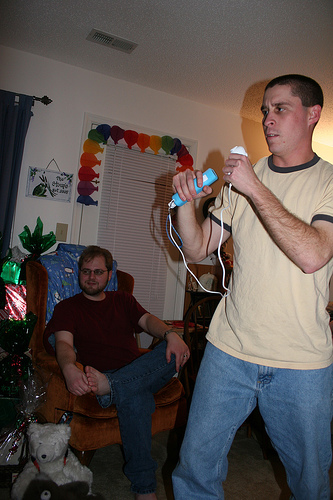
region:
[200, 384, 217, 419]
man wearing blue jeans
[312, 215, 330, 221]
blue lining on sleeve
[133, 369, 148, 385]
man wearing dark blue jeans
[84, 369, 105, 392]
man with bare foot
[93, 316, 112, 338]
man wearing burgandy tshirt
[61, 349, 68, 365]
man has hair on arm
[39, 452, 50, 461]
bear has black nose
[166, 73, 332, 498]
man playing a game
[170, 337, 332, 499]
the pants are blue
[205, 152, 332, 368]
a black and yellow shirt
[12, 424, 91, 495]
teddy bear on floor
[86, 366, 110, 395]
the man is barefoot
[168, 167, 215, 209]
blue and white controller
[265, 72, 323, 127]
the hair is short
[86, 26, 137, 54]
vent on the ceiling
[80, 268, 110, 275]
the man has glasses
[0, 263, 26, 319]
a wrapped present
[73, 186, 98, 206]
paper balloon over window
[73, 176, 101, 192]
paper balloon over window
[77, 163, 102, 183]
paper balloon over window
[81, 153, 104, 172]
paper balloon over window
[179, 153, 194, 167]
paper balloon over window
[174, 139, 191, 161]
paper balloon over window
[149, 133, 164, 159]
paper balloon over window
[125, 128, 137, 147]
paper balloon over window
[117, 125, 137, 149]
paper balloon over window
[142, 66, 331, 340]
man holding game controls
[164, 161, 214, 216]
game control is blue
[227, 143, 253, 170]
game control is white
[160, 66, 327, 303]
man has short hair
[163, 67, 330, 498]
man wears blue jeans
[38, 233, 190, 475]
man sits on a chair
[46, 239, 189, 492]
man cross his legs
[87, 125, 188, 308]
the window has blinds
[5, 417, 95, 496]
a white teddy bear on the floor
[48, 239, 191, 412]
man wears glasses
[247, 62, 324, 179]
head of a person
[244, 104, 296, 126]
eye of a person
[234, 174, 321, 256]
arm of a person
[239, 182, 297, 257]
an arm of a person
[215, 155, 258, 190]
hand of a person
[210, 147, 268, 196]
a hand of a person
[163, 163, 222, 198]
hand of a person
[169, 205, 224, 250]
arm of a person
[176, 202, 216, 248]
an arm of a person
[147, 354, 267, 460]
leg of a person